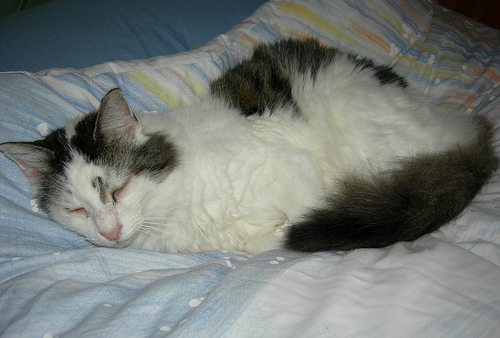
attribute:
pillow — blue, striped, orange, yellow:
[371, 24, 455, 63]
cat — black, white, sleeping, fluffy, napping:
[14, 72, 472, 271]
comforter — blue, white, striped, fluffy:
[219, 23, 238, 27]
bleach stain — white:
[390, 26, 483, 104]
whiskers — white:
[147, 213, 194, 241]